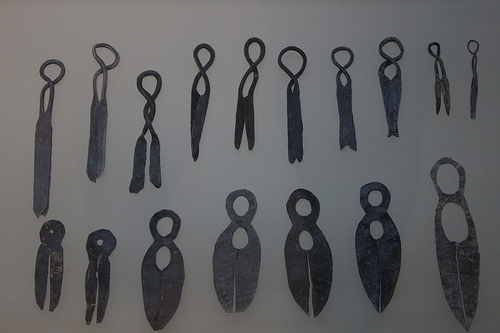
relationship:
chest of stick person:
[151, 242, 173, 269] [141, 208, 184, 328]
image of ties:
[154, 162, 389, 333] [74, 75, 447, 185]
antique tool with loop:
[273, 36, 318, 169] [274, 39, 309, 83]